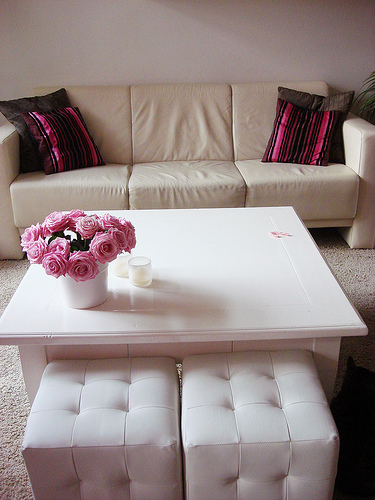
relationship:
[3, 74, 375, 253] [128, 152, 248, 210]
couch has a cushion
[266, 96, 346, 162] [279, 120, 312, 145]
pillow has stripes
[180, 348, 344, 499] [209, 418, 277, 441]
ottoman covered in cloth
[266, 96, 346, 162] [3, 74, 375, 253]
pillow on top of couch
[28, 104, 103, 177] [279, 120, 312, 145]
pillow has stripes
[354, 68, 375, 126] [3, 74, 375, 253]
plant beside sofa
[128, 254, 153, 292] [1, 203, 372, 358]
candle holder on top of table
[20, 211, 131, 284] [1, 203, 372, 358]
flowers are on top of table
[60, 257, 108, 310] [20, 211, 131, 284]
container has flowers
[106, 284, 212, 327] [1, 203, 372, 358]
shadow on top of table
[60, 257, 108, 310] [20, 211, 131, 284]
vase has roses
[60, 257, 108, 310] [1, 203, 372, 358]
vase on top of table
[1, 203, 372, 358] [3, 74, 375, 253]
table in front of couch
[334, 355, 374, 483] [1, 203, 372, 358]
cat sitting next to table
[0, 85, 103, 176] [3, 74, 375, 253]
pillow on top of couch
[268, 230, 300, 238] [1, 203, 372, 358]
petals are on tope of table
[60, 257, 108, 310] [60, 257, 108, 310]
vase made out of container